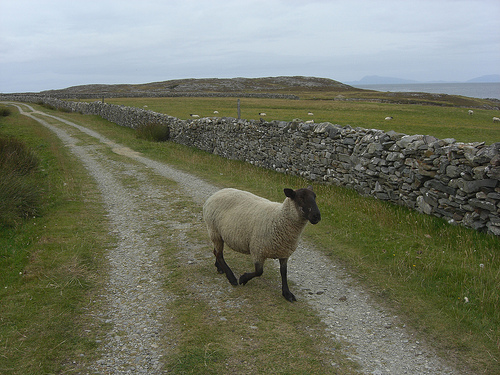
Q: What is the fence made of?
A: Rocks.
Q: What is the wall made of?
A: Rocks.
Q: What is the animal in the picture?
A: Sheep.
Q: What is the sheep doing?
A: Running.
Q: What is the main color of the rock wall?
A: Grey.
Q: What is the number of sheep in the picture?
A: 1.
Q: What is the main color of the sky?
A: Blue.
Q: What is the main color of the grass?
A: Green.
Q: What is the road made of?
A: Dirt and stone.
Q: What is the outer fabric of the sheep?
A: Wool.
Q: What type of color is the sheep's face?
A: Black.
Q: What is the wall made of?
A: Stone.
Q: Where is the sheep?
A: On a road.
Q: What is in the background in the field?
A: Sheep.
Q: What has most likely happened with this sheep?
A: Escaped.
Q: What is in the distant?
A: Hills.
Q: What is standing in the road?
A: A sheep.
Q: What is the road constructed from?
A: Gravel.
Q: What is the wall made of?
A: Rocks.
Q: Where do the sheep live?
A: Behind the stone fence.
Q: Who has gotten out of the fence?
A: One black and white sheep.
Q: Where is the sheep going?
A: Across the road.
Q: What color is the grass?
A: Green.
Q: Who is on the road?
A: A sheep.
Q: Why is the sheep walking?
A: To get somewhere.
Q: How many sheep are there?
A: One.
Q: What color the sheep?
A: White.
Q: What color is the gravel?
A: Gray.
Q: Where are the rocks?
A: Between the grass patches.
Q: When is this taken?
A: During the day.